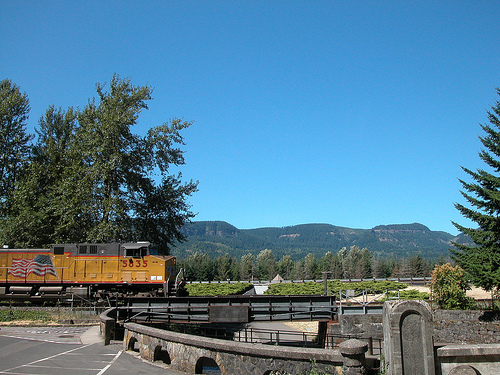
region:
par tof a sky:
[335, 83, 397, 165]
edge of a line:
[191, 328, 220, 366]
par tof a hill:
[288, 192, 338, 274]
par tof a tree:
[166, 170, 205, 247]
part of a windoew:
[123, 208, 157, 255]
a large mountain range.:
[171, 215, 476, 275]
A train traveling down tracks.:
[1, 235, 179, 298]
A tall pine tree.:
[431, 98, 498, 293]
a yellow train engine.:
[1, 216, 208, 305]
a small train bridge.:
[89, 294, 499, 374]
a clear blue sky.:
[0, 0, 497, 238]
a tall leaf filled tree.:
[0, 68, 217, 246]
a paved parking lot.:
[3, 316, 170, 373]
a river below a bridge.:
[254, 319, 329, 354]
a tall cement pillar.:
[382, 292, 452, 373]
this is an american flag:
[0, 248, 117, 288]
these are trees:
[5, 72, 205, 254]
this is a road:
[13, 330, 141, 372]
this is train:
[3, 242, 167, 289]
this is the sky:
[221, 32, 451, 209]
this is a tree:
[450, 92, 497, 304]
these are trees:
[186, 247, 418, 282]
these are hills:
[183, 213, 441, 256]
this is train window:
[51, 243, 68, 263]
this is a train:
[4, 240, 176, 296]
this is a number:
[121, 256, 149, 268]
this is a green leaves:
[82, 217, 117, 233]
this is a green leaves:
[473, 208, 499, 271]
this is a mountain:
[261, 223, 350, 285]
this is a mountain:
[372, 223, 433, 299]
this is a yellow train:
[4, 240, 182, 293]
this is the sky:
[280, 32, 363, 91]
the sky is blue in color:
[321, 89, 455, 173]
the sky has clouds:
[252, 202, 277, 230]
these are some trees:
[6, 70, 192, 253]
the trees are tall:
[10, 74, 143, 236]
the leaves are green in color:
[85, 129, 100, 151]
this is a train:
[12, 232, 185, 301]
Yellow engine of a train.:
[2, 243, 184, 296]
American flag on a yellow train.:
[6, 254, 63, 279]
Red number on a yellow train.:
[121, 257, 148, 271]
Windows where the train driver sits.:
[121, 241, 158, 257]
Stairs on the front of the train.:
[166, 265, 185, 297]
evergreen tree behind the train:
[236, 247, 252, 283]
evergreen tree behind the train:
[255, 245, 276, 285]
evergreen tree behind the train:
[265, 260, 278, 286]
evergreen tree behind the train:
[273, 251, 294, 284]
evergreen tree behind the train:
[286, 256, 306, 281]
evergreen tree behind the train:
[320, 243, 337, 283]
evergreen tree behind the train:
[331, 240, 347, 280]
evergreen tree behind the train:
[355, 255, 370, 280]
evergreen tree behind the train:
[347, 239, 362, 283]